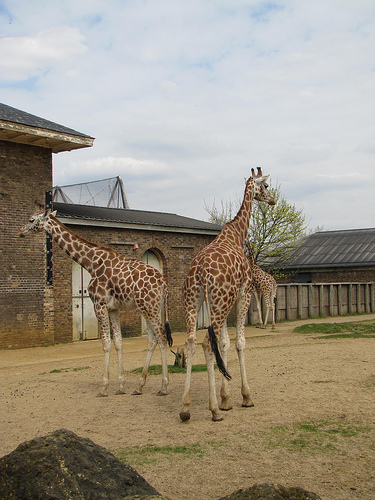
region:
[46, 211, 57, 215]
The ears of the giraffe on the left.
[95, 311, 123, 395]
The front legs of the giraffe on the left.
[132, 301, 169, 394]
The back legs of the giraffe on the left.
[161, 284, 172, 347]
The tail of the giraffe on the left.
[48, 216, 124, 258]
The mane of the giraffe on the left.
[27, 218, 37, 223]
The eye of the giraffe on the left.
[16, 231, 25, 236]
The mouth of the giraffe on the left.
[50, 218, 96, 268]
The neck of the giraffe on the left.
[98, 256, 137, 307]
The spots in the giraffe's stomach area.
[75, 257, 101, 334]
The door on the brick building.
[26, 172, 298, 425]
three giraffes standing in a field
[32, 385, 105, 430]
brown dirt ground of the pen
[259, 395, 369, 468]
sparse green grass on the ground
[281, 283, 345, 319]
grey wood fence of the pen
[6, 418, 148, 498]
large black boulder on the ground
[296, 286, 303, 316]
grey wood post of the fence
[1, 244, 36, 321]
brown brick wall of the building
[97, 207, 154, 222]
black roof of the building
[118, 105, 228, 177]
white cloudy skies over the pen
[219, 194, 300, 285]
tree growing outside of the fence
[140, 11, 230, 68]
this is the sky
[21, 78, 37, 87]
the sky is blue in color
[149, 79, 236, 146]
the sky has clouds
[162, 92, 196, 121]
the clouds are big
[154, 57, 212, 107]
the clouds are white in color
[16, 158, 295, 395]
these are some giraffes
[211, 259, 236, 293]
the fur is brown in color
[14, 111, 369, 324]
this is a building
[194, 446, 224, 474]
this is the ground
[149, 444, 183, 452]
this is the grass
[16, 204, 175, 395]
A brown and white giraffe fully visible pointing left.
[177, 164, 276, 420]
A tall brown and white giraffe pointing to the right.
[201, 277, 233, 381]
A black, white and brown tail on a giraffe facing right.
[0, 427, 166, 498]
A large black pile of dirt.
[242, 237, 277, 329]
A brown and white giraffe clear over beside a building.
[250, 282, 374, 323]
A long concrete wall.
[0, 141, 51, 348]
Tall brick section of building.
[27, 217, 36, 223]
Black eye of a giraffe close to the tall brick building.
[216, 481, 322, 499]
A smaller black pile of dirt.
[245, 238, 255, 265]
Neck of a giraffe further away.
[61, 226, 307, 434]
girrafes standing beside buildings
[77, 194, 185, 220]
roof is blck in color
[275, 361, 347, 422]
the floor is sandy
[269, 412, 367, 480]
the floor has some grases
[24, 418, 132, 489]
a lump of black sand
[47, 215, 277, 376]
giraffes are brown and white in color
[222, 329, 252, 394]
the legs are light brown in color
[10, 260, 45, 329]
the wall is blck and brown bricked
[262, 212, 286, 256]
the tree leafs is green in color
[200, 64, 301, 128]
sky is covered by white clouds